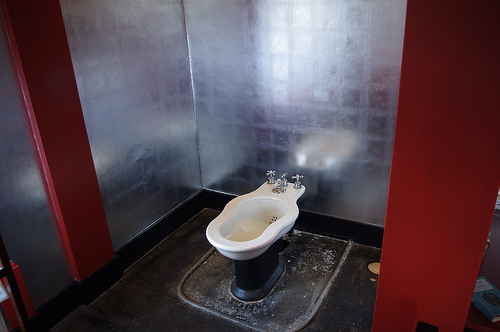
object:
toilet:
[204, 169, 309, 305]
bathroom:
[0, 0, 499, 331]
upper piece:
[205, 178, 305, 261]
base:
[230, 238, 291, 301]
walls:
[0, 0, 203, 331]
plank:
[0, 0, 117, 283]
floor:
[33, 206, 383, 332]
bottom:
[176, 228, 353, 331]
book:
[470, 276, 499, 322]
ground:
[0, 209, 499, 331]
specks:
[305, 278, 319, 288]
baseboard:
[22, 188, 381, 332]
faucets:
[286, 174, 303, 190]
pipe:
[0, 246, 37, 330]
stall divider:
[370, 0, 499, 331]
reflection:
[288, 124, 359, 203]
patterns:
[0, 1, 499, 331]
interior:
[216, 195, 288, 241]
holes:
[268, 217, 274, 221]